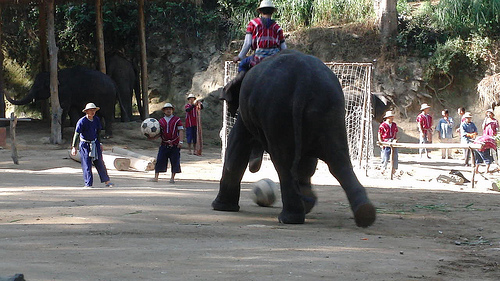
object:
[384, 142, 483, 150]
planks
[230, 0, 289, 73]
man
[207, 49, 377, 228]
elephant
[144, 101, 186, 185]
man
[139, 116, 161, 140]
soccer ball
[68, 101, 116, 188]
man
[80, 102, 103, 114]
brimmed hat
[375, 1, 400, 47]
tree trunk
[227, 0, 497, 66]
ledge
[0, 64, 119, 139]
elephants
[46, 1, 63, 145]
tree trunk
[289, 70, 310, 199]
elephants tail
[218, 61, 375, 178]
goal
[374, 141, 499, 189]
table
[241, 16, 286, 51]
shirt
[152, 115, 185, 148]
shirts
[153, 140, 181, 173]
shorts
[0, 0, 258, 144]
trees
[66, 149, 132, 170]
logs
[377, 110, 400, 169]
people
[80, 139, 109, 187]
pants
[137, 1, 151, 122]
tree trunks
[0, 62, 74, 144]
shade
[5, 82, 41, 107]
trunk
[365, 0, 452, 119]
roots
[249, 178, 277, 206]
ball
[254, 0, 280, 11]
hat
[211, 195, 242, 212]
large foot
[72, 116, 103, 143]
shirt